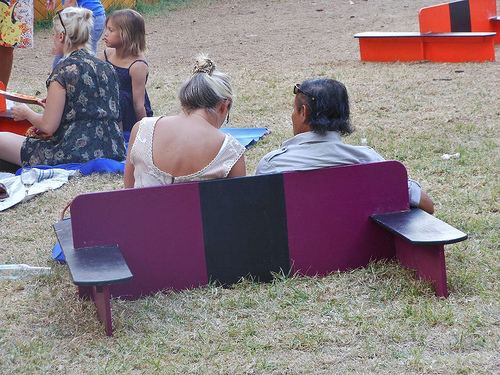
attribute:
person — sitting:
[3, 7, 125, 165]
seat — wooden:
[183, 161, 353, 268]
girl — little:
[92, 3, 154, 137]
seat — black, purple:
[47, 159, 469, 340]